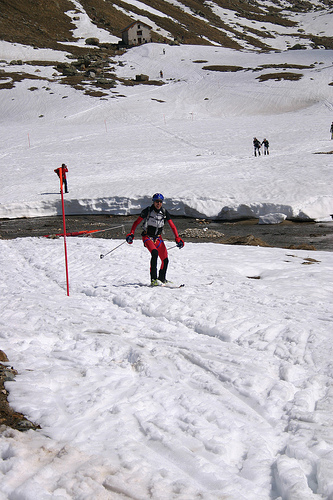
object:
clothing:
[125, 204, 184, 280]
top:
[138, 204, 172, 238]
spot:
[245, 274, 260, 280]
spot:
[283, 258, 291, 262]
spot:
[285, 253, 295, 257]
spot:
[301, 260, 313, 266]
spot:
[302, 260, 319, 263]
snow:
[1, 1, 321, 498]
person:
[252, 136, 261, 154]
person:
[259, 136, 270, 154]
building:
[122, 20, 153, 49]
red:
[53, 165, 68, 177]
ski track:
[83, 327, 126, 337]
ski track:
[174, 348, 276, 426]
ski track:
[121, 414, 225, 490]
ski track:
[1, 381, 140, 495]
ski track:
[138, 334, 208, 345]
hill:
[1, 1, 333, 100]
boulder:
[57, 61, 70, 69]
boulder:
[88, 69, 96, 78]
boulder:
[66, 53, 83, 59]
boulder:
[84, 36, 100, 45]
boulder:
[101, 59, 110, 67]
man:
[125, 193, 184, 286]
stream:
[14, 213, 299, 245]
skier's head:
[151, 191, 163, 210]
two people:
[252, 135, 269, 158]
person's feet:
[150, 279, 165, 287]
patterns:
[116, 291, 304, 386]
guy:
[54, 162, 69, 192]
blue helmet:
[151, 192, 165, 200]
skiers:
[158, 41, 167, 83]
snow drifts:
[129, 39, 319, 112]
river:
[8, 208, 328, 252]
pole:
[57, 169, 72, 295]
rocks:
[0, 352, 42, 430]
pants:
[143, 232, 170, 284]